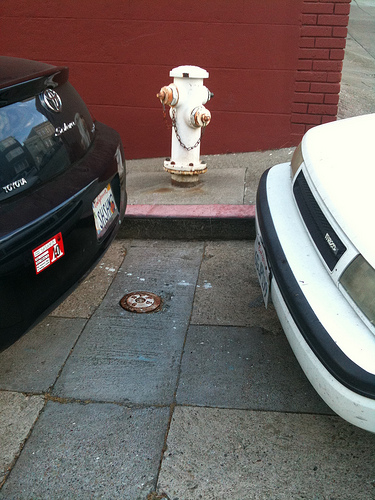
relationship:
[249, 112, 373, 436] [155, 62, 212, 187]
cars by hydrant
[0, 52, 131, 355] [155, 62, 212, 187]
cars by hydrant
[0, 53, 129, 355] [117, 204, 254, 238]
cars by curb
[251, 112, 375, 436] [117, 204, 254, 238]
cars by curb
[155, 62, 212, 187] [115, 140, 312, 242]
hydrant on sidewalk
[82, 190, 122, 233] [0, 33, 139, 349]
license plate on car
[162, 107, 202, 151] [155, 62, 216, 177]
chain on fire hydrant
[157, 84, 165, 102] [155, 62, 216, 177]
cap on fire hydrant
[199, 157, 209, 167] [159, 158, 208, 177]
screw on base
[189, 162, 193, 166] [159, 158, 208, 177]
screw on base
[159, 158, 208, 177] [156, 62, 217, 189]
base on hydrant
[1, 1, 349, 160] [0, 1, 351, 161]
wall on building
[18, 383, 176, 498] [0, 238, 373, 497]
weeds growing in cracks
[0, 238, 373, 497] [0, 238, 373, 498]
cracks on road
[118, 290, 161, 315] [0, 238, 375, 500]
hole cover in road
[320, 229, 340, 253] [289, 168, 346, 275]
mazda trademark on grill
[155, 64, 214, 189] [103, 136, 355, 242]
hydrant on sidewalk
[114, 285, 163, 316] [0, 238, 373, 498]
hole cover on road